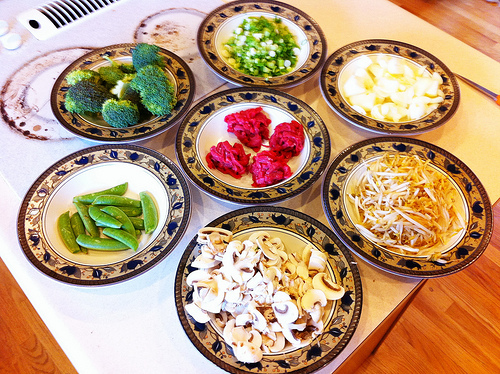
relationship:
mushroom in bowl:
[181, 237, 333, 349] [172, 201, 392, 366]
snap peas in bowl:
[54, 182, 161, 254] [9, 138, 196, 288]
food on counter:
[146, 85, 416, 259] [2, 8, 482, 357]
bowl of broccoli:
[15, 140, 196, 288] [66, 41, 176, 126]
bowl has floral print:
[9, 126, 213, 303] [11, 144, 198, 287]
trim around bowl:
[331, 281, 363, 351] [178, 202, 361, 369]